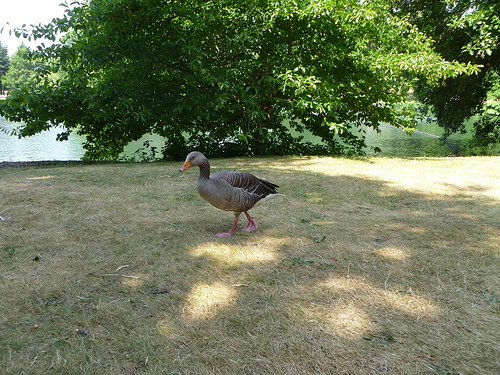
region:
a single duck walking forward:
[177, 148, 278, 239]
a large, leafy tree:
[0, 0, 485, 162]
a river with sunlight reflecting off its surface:
[0, 96, 499, 161]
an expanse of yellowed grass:
[0, 153, 497, 373]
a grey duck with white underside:
[177, 148, 280, 239]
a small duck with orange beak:
[177, 148, 279, 239]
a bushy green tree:
[392, 0, 499, 157]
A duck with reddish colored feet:
[177, 149, 278, 239]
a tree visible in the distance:
[0, 41, 52, 91]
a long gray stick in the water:
[371, 118, 458, 155]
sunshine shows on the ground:
[294, 154, 497, 219]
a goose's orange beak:
[175, 145, 195, 180]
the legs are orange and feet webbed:
[201, 207, 276, 242]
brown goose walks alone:
[170, 140, 291, 255]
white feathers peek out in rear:
[245, 170, 300, 220]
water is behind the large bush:
[0, 85, 496, 175]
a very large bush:
[0, 11, 455, 151]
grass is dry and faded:
[0, 165, 495, 370]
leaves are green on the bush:
[115, 10, 335, 120]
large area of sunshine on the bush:
[280, 0, 496, 89]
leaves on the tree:
[259, 104, 274, 116]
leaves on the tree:
[332, 58, 352, 78]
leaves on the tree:
[107, 68, 136, 95]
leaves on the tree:
[401, 60, 423, 81]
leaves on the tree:
[254, 113, 269, 125]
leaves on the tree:
[253, 33, 273, 50]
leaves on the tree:
[31, 103, 51, 123]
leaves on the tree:
[131, 58, 144, 73]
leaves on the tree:
[220, 15, 245, 39]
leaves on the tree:
[252, 41, 263, 56]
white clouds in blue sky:
[8, 0, 45, 17]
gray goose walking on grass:
[176, 137, 271, 230]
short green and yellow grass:
[12, 172, 63, 205]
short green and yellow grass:
[186, 281, 229, 311]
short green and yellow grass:
[273, 265, 314, 312]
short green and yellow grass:
[363, 211, 410, 254]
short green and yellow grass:
[45, 312, 112, 355]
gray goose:
[164, 150, 285, 241]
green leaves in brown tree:
[16, 68, 51, 89]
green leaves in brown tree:
[106, 32, 147, 76]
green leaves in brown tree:
[124, 52, 184, 136]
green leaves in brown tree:
[190, 20, 237, 62]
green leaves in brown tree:
[186, 79, 234, 111]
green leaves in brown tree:
[243, 20, 280, 62]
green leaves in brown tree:
[254, 58, 295, 118]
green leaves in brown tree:
[349, 3, 377, 53]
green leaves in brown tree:
[290, 69, 341, 113]